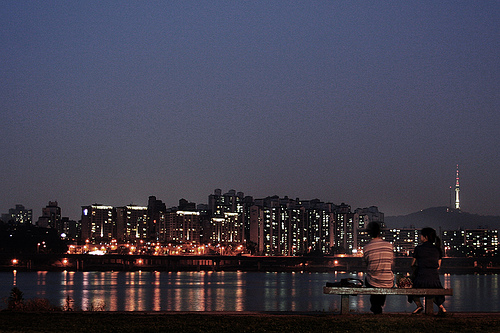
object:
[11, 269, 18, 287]
lights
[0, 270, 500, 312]
water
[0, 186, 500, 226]
skyline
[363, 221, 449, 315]
couple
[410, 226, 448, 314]
person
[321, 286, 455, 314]
bench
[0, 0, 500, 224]
sky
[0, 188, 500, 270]
city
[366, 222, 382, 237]
dark hair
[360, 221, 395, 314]
man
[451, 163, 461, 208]
tower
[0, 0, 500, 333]
background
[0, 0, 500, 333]
night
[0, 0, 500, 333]
time